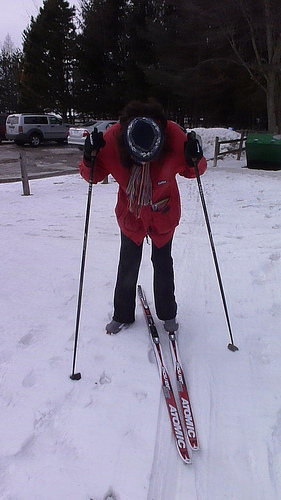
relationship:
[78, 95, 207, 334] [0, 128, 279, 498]
person looking snow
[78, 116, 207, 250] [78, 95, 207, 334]
coat on person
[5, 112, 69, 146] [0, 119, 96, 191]
vehicle in parking lot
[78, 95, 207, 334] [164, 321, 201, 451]
person at ski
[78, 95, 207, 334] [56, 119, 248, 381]
person holding ski poles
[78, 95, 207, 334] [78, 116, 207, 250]
person wearing coat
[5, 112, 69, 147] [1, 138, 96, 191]
vehicle in parking lot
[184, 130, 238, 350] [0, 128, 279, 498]
pole in snow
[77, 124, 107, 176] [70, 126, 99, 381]
hand on ski poles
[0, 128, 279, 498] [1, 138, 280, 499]
snow covering ground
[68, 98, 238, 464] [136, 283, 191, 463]
person looking down at ski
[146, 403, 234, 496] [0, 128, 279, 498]
tracks in snow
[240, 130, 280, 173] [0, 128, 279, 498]
container in snow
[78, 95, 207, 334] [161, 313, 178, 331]
person wearing boot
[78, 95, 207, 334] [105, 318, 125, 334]
person wearing boot